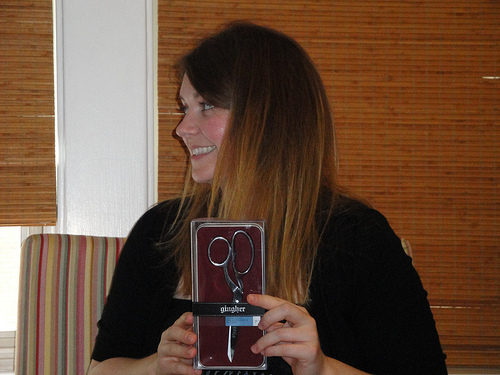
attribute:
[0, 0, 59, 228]
window shade — brown, wooden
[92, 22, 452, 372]
woman — smiling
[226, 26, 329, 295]
hair — brown, long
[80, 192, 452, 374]
shirt — black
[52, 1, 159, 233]
wall — white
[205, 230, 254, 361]
scissors — sharp, silver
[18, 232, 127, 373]
seat cushion — colorful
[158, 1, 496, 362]
shade — wooden